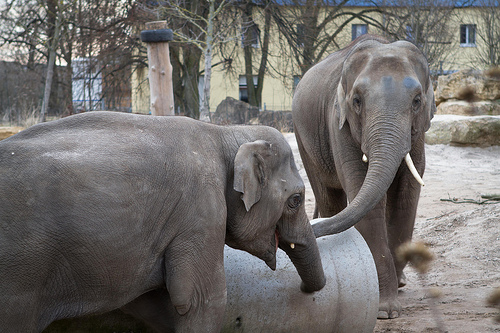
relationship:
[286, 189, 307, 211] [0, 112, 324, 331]
eye on elephant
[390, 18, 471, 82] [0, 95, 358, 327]
tree behind elephant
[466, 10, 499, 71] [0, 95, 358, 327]
tree behind elephant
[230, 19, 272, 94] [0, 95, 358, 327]
tree behind elephant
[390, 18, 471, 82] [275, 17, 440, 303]
tree behind elephant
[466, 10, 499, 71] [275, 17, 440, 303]
tree behind elephant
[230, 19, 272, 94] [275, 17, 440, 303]
tree behind elephant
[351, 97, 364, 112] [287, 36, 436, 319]
eye of elephant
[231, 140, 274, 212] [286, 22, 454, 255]
ear of elephant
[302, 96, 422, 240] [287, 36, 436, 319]
trunk of elephant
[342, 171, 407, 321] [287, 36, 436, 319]
leg of elephant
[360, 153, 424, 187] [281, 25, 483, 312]
tusk of elephant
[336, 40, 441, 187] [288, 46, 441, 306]
head of elephant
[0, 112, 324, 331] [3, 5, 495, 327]
elephant in pen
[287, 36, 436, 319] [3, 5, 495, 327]
elephant in pen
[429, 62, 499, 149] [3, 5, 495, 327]
stones in pen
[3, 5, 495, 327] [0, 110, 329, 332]
pen of elephant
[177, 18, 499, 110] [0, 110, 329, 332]
building behind elephant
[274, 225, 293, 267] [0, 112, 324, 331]
mouth on elephant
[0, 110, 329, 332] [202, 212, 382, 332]
elephant next to tube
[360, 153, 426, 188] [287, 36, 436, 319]
tusk are on elephant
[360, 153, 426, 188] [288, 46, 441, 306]
tusk on elephant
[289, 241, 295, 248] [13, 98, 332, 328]
tusk on elephant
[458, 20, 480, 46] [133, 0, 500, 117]
window on building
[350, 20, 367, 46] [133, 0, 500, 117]
window on building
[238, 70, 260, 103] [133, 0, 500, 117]
window on building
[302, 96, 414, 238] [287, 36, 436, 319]
trunk on elephant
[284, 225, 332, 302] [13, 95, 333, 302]
trunk on elephant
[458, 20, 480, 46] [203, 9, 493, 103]
window on house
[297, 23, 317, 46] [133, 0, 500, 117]
window on building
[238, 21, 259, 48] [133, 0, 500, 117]
window on building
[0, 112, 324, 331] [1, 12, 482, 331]
elephant standing in enclosure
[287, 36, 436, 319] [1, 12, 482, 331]
elephant walking in enclosure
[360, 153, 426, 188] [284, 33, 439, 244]
tusk belonging to elephant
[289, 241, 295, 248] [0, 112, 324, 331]
tusk belonging to elephant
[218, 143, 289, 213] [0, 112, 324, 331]
ear belonging to elephant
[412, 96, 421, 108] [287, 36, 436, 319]
eye belonging to elephant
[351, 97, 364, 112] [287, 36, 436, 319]
eye belonging to elephant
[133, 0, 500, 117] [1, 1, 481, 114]
building standing in background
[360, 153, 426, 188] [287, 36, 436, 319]
tusk belonging to elephant